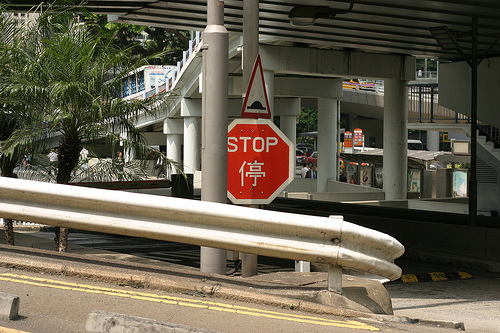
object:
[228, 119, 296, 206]
sign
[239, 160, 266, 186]
character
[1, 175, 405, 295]
rail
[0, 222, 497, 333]
street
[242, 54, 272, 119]
trafficsign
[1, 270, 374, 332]
line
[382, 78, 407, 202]
pillar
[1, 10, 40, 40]
building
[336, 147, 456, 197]
structure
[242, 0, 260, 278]
pole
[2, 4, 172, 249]
tree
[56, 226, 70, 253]
trunk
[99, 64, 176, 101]
bus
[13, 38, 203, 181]
bridge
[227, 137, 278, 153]
letter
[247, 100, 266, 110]
object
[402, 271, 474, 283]
bump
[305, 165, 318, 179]
man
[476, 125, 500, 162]
stairs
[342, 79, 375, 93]
taxi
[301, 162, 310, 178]
woman